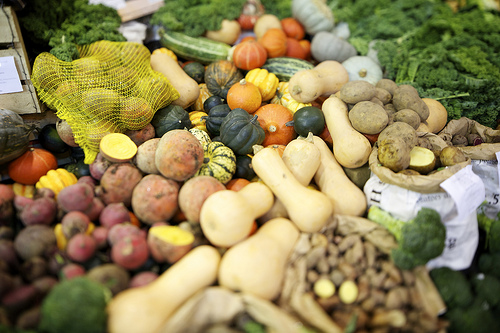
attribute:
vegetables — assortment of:
[37, 6, 463, 317]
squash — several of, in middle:
[208, 129, 356, 287]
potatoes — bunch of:
[10, 173, 170, 282]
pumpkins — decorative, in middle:
[189, 81, 296, 180]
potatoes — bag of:
[33, 30, 180, 140]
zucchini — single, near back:
[162, 24, 230, 57]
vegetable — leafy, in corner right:
[392, 20, 484, 109]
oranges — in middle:
[226, 77, 291, 131]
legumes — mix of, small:
[294, 220, 433, 324]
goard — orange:
[222, 34, 272, 75]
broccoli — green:
[359, 199, 455, 273]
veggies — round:
[50, 174, 153, 274]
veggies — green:
[364, 6, 491, 87]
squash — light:
[199, 181, 295, 293]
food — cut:
[97, 128, 142, 162]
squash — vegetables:
[235, 150, 330, 223]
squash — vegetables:
[202, 180, 273, 245]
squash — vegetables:
[228, 215, 298, 291]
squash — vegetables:
[106, 249, 224, 328]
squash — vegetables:
[304, 98, 406, 224]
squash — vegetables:
[240, 128, 305, 209]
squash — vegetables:
[311, 93, 368, 154]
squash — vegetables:
[282, 57, 349, 103]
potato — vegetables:
[368, 117, 423, 163]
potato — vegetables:
[342, 96, 393, 133]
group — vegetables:
[195, 133, 424, 326]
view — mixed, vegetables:
[65, 10, 443, 294]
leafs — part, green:
[39, 273, 105, 324]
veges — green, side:
[375, 16, 478, 108]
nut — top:
[42, 44, 189, 131]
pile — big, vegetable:
[148, 129, 213, 178]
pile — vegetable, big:
[141, 141, 204, 179]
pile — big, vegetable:
[129, 163, 193, 229]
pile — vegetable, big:
[92, 160, 168, 206]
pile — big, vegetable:
[97, 200, 143, 242]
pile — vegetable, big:
[105, 215, 143, 243]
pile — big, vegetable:
[50, 171, 110, 215]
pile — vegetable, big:
[57, 231, 97, 259]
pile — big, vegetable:
[18, 193, 55, 221]